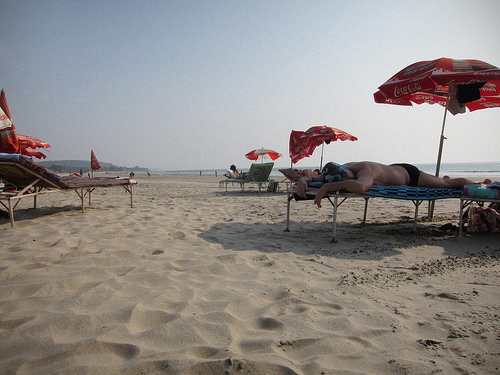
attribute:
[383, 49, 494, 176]
umbrella — large, red, white, open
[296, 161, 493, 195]
person — sun bathing, laying, lying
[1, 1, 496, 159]
sky — blue, clear, pretty, cloudless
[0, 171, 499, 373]
beach — full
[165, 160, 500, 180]
ocean — blue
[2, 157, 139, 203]
chair — brown, wooden, empty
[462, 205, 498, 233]
bag — large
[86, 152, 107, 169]
umbrella — red, white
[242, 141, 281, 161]
umbrella — red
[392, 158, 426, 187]
bathing suit — black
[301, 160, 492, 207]
man — sun bathing, lying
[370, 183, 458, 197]
towel — blue